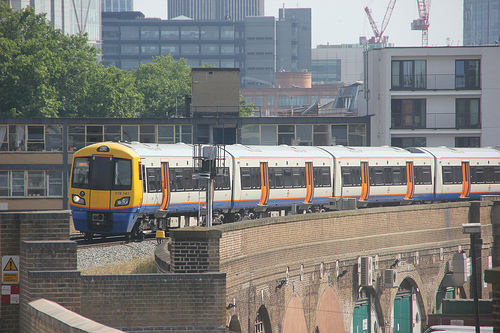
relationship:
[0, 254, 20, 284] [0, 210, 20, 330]
sign posted on wall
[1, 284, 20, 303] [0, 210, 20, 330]
sign posted on wall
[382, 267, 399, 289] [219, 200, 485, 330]
air conditioning mounted on wall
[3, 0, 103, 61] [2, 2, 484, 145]
building standing in distance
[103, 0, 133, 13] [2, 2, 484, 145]
building standing in distance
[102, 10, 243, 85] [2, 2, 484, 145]
building standing in distance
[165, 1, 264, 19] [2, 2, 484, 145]
building standing in distance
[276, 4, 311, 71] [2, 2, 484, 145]
building standing in distance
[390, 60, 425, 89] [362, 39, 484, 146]
window adorning building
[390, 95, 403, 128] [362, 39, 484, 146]
window adorning building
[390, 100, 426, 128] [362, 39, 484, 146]
window adorning building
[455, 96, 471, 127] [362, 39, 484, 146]
window adorning building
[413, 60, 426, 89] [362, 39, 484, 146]
window adorning building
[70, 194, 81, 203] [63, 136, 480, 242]
light mounted on train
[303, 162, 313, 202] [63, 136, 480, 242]
door leading to train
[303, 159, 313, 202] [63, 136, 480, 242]
door leading to train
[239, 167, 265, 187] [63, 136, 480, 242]
passenger window built into train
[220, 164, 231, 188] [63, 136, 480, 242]
passenger window built into train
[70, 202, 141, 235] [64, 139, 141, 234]
paint covering front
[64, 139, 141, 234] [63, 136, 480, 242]
front belonging to train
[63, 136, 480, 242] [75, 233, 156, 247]
train riding on train track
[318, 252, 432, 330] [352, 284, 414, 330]
arches over doors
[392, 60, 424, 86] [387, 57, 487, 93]
sliding door to balcony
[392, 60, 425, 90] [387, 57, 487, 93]
sliding door to balcony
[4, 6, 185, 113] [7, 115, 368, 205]
treetops rising over building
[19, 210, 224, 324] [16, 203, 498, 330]
brick wall of railway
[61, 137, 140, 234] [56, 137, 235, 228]
front of engine car